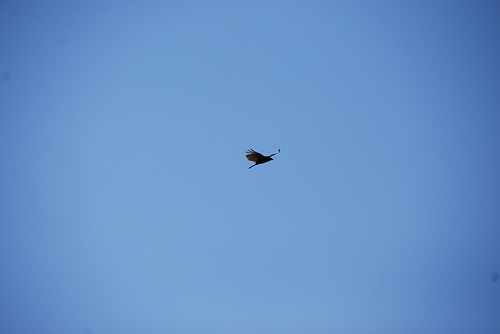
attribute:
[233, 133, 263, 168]
feathers — several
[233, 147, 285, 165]
feathers — long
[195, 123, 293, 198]
bird — dark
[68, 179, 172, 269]
sky — blue, clear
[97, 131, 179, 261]
sky — clear, cloudless, blue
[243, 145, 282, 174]
bird — black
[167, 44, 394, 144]
sky — clear, blue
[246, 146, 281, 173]
bird — small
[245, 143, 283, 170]
bird — lonely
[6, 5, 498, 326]
sky — cloudless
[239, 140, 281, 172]
bird — alone, flying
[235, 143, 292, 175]
bird — flying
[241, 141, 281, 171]
bird — black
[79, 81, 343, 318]
sky — blue and clear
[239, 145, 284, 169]
bird — alone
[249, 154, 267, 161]
feathers — long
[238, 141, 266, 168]
wing span — large